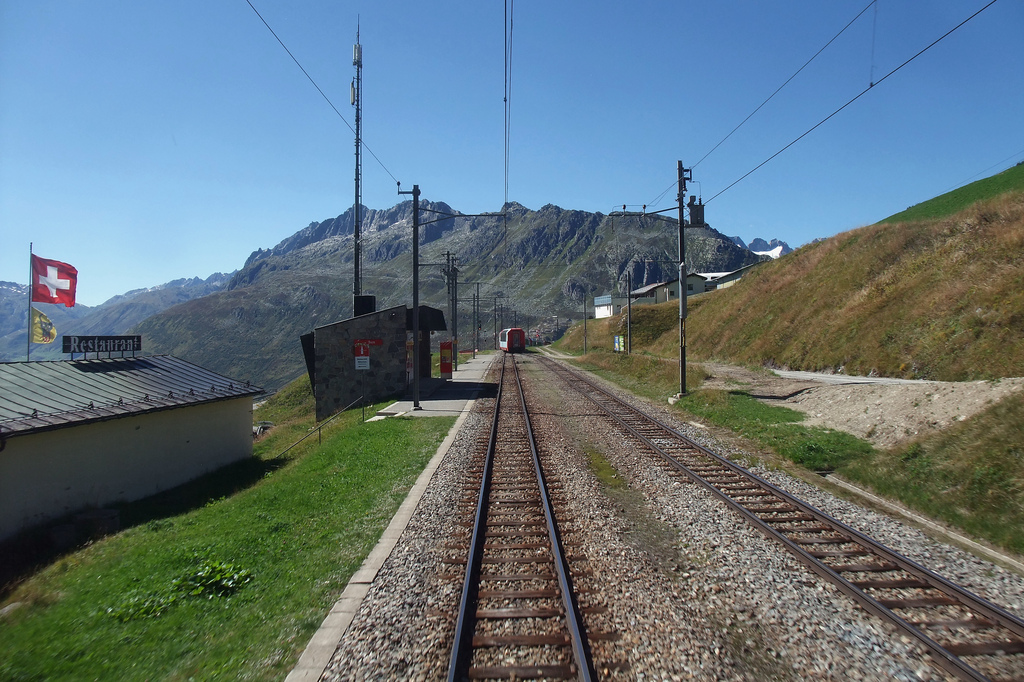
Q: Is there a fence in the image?
A: No, there are no fences.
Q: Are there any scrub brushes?
A: No, there are no scrub brushes.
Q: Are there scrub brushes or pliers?
A: No, there are no scrub brushes or pliers.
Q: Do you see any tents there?
A: No, there are no tents.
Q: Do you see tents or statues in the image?
A: No, there are no tents or statues.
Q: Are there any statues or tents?
A: No, there are no tents or statues.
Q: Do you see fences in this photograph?
A: No, there are no fences.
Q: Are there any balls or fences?
A: No, there are no fences or balls.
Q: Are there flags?
A: Yes, there is a flag.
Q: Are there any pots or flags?
A: Yes, there is a flag.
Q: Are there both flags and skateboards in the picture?
A: No, there is a flag but no skateboards.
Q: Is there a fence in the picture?
A: No, there are no fences.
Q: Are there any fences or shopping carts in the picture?
A: No, there are no fences or shopping carts.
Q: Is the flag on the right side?
A: No, the flag is on the left of the image.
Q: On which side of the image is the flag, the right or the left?
A: The flag is on the left of the image.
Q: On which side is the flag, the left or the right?
A: The flag is on the left of the image.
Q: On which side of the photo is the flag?
A: The flag is on the left of the image.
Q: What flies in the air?
A: The flag flies in the air.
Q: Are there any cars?
A: No, there are no cars.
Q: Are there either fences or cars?
A: No, there are no cars or fences.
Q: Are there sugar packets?
A: No, there are no sugar packets.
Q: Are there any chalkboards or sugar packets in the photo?
A: No, there are no sugar packets or chalkboards.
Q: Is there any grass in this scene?
A: Yes, there is grass.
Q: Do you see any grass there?
A: Yes, there is grass.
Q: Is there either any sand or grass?
A: Yes, there is grass.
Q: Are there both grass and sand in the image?
A: No, there is grass but no sand.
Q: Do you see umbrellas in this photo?
A: No, there are no umbrellas.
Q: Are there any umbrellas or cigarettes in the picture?
A: No, there are no umbrellas or cigarettes.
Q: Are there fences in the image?
A: No, there are no fences.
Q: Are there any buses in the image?
A: No, there are no buses.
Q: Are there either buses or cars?
A: No, there are no buses or cars.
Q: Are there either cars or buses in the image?
A: No, there are no buses or cars.